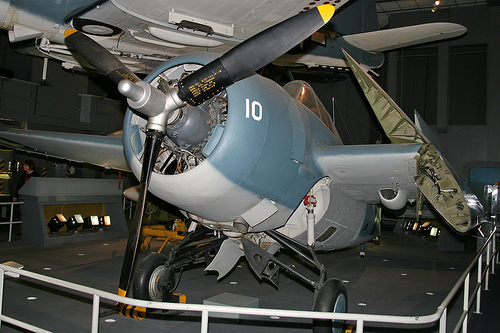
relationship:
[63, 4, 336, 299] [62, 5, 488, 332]
propeller in front of plane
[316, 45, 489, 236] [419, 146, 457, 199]
wing with wires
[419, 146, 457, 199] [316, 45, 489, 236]
wires on wing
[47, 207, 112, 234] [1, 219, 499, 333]
lights on floor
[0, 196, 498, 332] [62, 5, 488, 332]
railing surrounds plane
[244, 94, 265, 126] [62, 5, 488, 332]
number on side of plane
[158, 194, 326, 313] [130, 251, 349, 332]
frame supports wheels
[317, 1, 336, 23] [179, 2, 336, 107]
tip on blade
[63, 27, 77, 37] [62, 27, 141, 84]
tip on blade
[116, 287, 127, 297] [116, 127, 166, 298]
tip on blade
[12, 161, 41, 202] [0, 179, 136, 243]
person in aisle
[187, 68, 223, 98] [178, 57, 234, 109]
print on base of propeller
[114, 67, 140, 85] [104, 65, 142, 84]
print on base of propeller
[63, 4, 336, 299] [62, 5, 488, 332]
propeller on plane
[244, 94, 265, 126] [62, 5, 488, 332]
number 10 on plane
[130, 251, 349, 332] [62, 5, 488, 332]
wheels on plane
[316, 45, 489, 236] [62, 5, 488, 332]
wing on plane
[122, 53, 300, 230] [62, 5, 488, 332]
engine of plane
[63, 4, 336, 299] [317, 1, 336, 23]
propeller with yellow tip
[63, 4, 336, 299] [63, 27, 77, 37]
propeller with yellow tip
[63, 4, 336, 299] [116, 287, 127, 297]
propeller with yellow tip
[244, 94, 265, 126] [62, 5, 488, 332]
number on plane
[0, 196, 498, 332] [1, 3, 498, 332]
railing surrounds display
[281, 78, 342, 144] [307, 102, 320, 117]
plastic covering pilot's seat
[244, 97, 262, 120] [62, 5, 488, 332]
number on plane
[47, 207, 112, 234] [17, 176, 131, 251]
lights on wall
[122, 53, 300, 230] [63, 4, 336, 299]
engine of propeller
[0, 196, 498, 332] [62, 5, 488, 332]
railing around plane